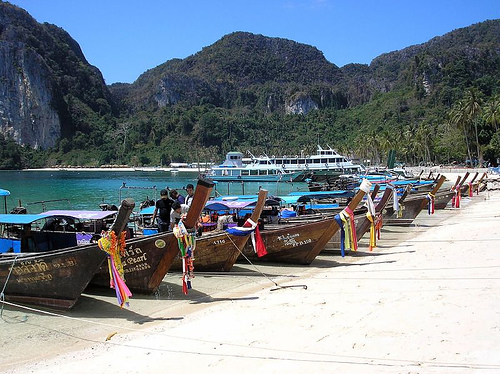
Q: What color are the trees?
A: Green.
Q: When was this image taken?
A: Daytime.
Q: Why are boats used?
A: Transportation.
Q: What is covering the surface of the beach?
A: Sand.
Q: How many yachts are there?
A: One.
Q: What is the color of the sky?
A: Blue.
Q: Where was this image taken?
A: At a lake.